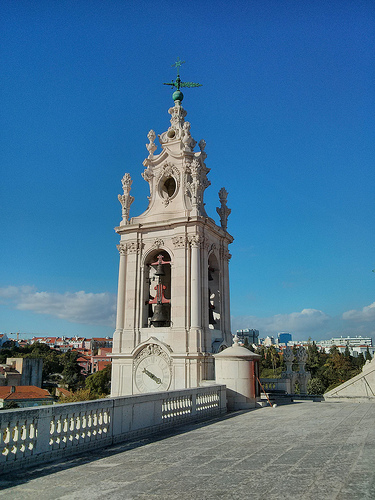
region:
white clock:
[126, 353, 172, 388]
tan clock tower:
[113, 76, 242, 380]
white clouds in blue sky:
[29, 219, 70, 255]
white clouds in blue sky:
[314, 218, 344, 248]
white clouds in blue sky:
[310, 263, 355, 299]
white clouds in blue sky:
[56, 289, 84, 316]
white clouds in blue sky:
[289, 303, 330, 336]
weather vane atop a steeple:
[163, 52, 189, 79]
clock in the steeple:
[126, 352, 179, 400]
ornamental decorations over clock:
[132, 345, 173, 359]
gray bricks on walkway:
[255, 434, 311, 489]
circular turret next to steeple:
[216, 352, 261, 390]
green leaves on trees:
[319, 346, 348, 389]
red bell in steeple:
[141, 287, 168, 299]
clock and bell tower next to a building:
[109, 56, 232, 396]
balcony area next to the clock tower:
[0, 388, 373, 497]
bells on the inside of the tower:
[142, 250, 175, 328]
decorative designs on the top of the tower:
[118, 128, 234, 232]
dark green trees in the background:
[1, 340, 367, 393]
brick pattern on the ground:
[0, 398, 373, 498]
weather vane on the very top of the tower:
[162, 58, 205, 101]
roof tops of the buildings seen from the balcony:
[1, 332, 109, 396]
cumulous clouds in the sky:
[1, 293, 370, 333]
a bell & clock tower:
[105, 35, 252, 486]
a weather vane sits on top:
[150, 53, 206, 111]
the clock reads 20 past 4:
[133, 345, 176, 401]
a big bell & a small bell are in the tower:
[148, 247, 176, 339]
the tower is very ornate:
[107, 101, 242, 370]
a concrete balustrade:
[11, 385, 262, 486]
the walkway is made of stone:
[244, 421, 358, 496]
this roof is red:
[2, 380, 44, 400]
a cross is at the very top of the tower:
[167, 52, 194, 80]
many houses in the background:
[29, 329, 101, 356]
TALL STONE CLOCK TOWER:
[105, 113, 222, 402]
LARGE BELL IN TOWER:
[149, 256, 166, 276]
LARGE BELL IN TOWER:
[151, 300, 167, 321]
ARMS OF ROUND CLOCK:
[143, 365, 165, 387]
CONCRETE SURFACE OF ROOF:
[123, 388, 346, 499]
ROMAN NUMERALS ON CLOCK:
[128, 351, 176, 394]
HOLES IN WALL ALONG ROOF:
[0, 387, 233, 478]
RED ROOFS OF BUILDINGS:
[30, 329, 114, 374]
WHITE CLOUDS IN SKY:
[255, 306, 368, 344]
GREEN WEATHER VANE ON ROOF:
[158, 73, 196, 100]